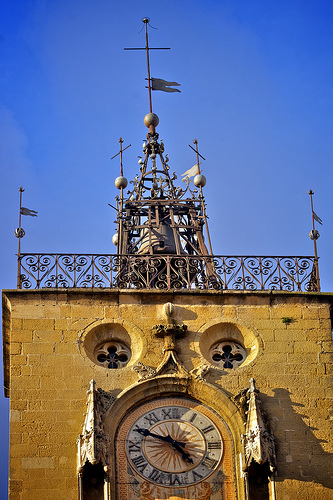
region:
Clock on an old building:
[107, 381, 232, 478]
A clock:
[118, 384, 210, 481]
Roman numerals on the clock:
[81, 367, 241, 488]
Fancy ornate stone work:
[75, 306, 276, 404]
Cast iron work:
[59, 178, 274, 319]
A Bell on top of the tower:
[133, 210, 191, 280]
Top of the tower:
[118, 16, 214, 147]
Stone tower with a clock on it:
[45, 261, 271, 498]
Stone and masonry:
[30, 301, 100, 411]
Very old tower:
[125, 284, 293, 354]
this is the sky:
[200, 12, 310, 105]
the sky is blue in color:
[226, 120, 285, 159]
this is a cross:
[124, 11, 175, 110]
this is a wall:
[10, 319, 81, 422]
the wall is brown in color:
[17, 355, 71, 459]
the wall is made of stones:
[13, 330, 73, 407]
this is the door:
[116, 403, 239, 499]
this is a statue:
[151, 301, 187, 368]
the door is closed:
[113, 420, 236, 495]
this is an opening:
[210, 334, 244, 364]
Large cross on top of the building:
[118, 11, 186, 114]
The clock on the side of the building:
[121, 406, 224, 489]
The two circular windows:
[78, 317, 258, 374]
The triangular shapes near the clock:
[60, 374, 274, 477]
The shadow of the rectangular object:
[262, 379, 331, 489]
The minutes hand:
[133, 425, 176, 443]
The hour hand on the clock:
[172, 442, 196, 464]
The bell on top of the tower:
[132, 214, 198, 285]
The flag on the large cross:
[142, 70, 182, 97]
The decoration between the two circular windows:
[148, 300, 190, 379]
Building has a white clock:
[86, 376, 263, 499]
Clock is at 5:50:
[107, 379, 254, 499]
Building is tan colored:
[24, 304, 331, 498]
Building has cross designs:
[76, 300, 279, 388]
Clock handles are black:
[134, 419, 201, 467]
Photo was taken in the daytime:
[4, 16, 325, 481]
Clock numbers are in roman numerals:
[112, 401, 248, 495]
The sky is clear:
[1, 9, 322, 241]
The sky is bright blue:
[5, 11, 323, 281]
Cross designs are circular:
[82, 322, 271, 376]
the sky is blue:
[21, 27, 80, 132]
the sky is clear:
[38, 45, 96, 132]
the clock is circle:
[120, 390, 230, 493]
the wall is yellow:
[18, 323, 65, 443]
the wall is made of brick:
[14, 312, 71, 444]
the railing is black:
[25, 233, 111, 300]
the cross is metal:
[119, 10, 198, 144]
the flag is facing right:
[142, 68, 191, 107]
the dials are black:
[136, 420, 197, 468]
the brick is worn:
[15, 320, 74, 446]